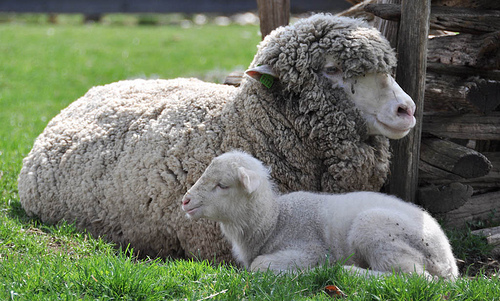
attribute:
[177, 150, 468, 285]
lamb — white, down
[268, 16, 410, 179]
sheep — dirty, down, wooly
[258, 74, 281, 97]
tag — green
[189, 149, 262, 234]
face — white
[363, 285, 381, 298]
grass — green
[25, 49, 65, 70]
pasture — green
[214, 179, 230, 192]
eye — closed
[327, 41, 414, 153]
face — white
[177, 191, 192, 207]
nose — pink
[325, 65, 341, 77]
eye — watching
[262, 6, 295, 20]
fence — wood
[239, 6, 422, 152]
head — gray